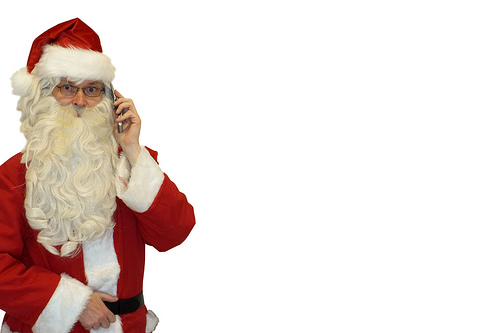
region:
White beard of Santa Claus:
[52, 178, 74, 215]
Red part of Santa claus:
[6, 235, 22, 255]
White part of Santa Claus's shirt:
[90, 257, 105, 278]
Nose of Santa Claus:
[72, 93, 89, 108]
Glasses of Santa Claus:
[60, 83, 105, 99]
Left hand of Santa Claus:
[113, 101, 140, 161]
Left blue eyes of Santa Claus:
[82, 82, 99, 97]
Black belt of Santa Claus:
[116, 298, 139, 311]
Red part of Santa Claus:
[59, 20, 90, 45]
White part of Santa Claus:
[46, 53, 83, 74]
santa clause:
[0, 10, 203, 332]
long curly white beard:
[15, 76, 130, 257]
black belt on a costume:
[91, 286, 148, 316]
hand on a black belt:
[78, 280, 122, 330]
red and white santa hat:
[6, 14, 121, 96]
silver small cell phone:
[109, 91, 130, 135]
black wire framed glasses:
[51, 80, 107, 97]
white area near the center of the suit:
[77, 205, 124, 331]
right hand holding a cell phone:
[108, 85, 146, 172]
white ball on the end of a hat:
[6, 63, 40, 102]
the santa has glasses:
[8, 71, 180, 330]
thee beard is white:
[23, 148, 118, 236]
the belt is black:
[102, 294, 146, 324]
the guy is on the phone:
[15, 67, 202, 330]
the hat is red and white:
[23, 27, 118, 69]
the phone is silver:
[102, 106, 138, 141]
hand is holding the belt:
[42, 273, 125, 329]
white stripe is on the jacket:
[72, 242, 144, 329]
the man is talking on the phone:
[1, 29, 163, 329]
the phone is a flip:
[100, 92, 142, 130]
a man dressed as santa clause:
[5, 5, 189, 332]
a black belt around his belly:
[28, 281, 158, 331]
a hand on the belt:
[71, 289, 121, 331]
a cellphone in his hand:
[108, 90, 141, 145]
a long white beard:
[15, 98, 155, 263]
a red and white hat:
[18, 13, 130, 94]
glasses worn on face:
[45, 81, 122, 113]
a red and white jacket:
[5, 130, 196, 332]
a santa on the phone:
[14, 18, 194, 331]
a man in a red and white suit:
[5, 22, 203, 331]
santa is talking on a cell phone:
[111, 93, 129, 138]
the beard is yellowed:
[15, 91, 125, 258]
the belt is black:
[94, 290, 149, 315]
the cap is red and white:
[10, 15, 115, 99]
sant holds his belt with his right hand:
[75, 282, 120, 331]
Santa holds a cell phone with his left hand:
[108, 80, 149, 165]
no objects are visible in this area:
[196, 15, 498, 331]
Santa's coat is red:
[0, 138, 197, 331]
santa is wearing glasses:
[56, 79, 104, 97]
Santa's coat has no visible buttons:
[74, 213, 126, 330]